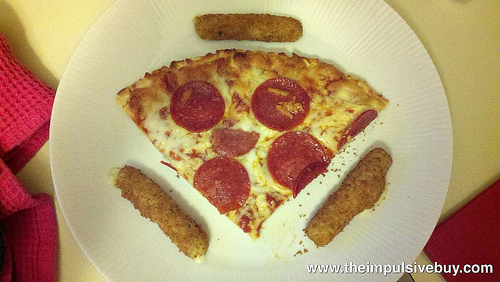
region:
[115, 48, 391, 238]
A large slice of pizza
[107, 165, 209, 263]
A small cheese stick.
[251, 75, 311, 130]
A pepperoni with cheese on top.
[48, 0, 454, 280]
A white plate on table.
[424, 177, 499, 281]
Red napkin on table.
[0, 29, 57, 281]
A red dish towl.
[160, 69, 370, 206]
slices of pepperoni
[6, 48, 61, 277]
red napkin on the left side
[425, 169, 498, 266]
red napkin on the right side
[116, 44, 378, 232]
slice of pizza on plate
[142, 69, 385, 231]
cheese on pizza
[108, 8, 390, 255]
three cheesesticks on the plate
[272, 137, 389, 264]
crumbs on the plate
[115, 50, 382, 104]
crust edge of the pizza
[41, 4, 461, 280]
food on plate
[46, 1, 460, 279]
food on paper plate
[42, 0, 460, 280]
food on white paper plate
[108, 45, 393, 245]
a pizza on plate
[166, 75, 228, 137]
a pepperoni on pizza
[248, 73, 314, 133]
a pepperoni on pizza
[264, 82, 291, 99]
cheese on pepperoni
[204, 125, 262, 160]
a pepperoni on pizza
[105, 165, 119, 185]
a melted cheese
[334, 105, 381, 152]
a pepperoni on pizza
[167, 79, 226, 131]
pepperoni on pizza slice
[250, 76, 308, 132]
pepperoni on pizza slice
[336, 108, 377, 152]
pepperoni on pizza slice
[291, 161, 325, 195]
pepperoni on pizza slice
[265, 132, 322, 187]
pepperoni on pizza slice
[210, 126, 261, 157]
pepperoni on pizza slice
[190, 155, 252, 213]
pepperoni on pizza slice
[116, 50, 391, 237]
pizza slice next to mozzarella stick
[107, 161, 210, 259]
mozzarella stick next to mozzarella stick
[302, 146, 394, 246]
mozzarella stick next to mozzarella stick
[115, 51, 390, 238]
A large pepperoni and cheese slice of pizza.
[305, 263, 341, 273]
White www in a web address.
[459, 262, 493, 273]
White .com on a web address.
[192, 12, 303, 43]
A cheese stick above a piece of pizza.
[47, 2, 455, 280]
A white plate with food on it.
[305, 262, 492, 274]
The web address www.theimpulsivebuy.com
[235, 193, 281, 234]
Bottom most piece of pepperoni buried under cheese.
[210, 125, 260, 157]
Middle red half a piece of pepperoni.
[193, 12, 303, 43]
Top cheese stick above the pizza on a plate.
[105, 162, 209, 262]
A brown cheese stick with cheese coming out both ends.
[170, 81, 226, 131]
pepperoni on slice of pizza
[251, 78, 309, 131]
pepperoni on slice of pizza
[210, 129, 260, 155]
pepperoni on slice of pizza